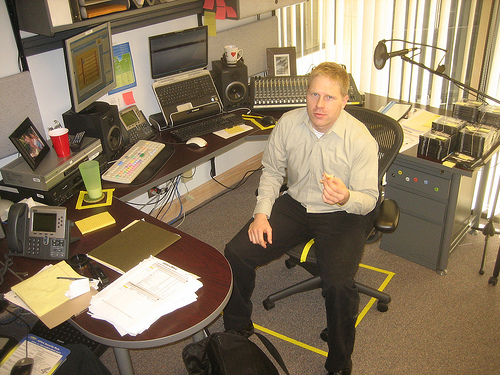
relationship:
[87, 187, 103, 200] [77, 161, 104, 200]
liquid in cup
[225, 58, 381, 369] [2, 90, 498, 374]
man surrounded by desk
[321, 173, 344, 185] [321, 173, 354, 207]
food in hand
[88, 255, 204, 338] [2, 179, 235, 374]
papers on table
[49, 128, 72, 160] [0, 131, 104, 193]
cup on device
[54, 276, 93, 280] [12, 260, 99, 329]
pen on pad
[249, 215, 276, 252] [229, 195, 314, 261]
hand on thigh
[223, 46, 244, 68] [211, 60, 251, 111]
mug on speaker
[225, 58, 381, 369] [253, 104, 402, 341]
man sitting on chair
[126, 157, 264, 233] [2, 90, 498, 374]
cords below desk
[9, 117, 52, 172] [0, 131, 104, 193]
photo on equipment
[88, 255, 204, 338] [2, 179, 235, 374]
papers on desk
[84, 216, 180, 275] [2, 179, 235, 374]
folder on desk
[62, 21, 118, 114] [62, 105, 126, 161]
monitor on speaker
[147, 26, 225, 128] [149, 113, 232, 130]
laptop on stand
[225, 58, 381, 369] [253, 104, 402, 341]
man on chair